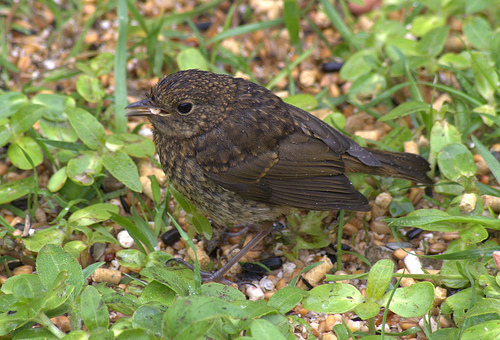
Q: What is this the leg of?
A: Small brown bird.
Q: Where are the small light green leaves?
A: On the ground.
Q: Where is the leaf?
A: On the ground.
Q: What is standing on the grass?
A: A bird.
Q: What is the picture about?
A: A bird.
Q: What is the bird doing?
A: Sitting.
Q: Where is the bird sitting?
A: On the ground.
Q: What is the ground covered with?
A: Grass, leaves and stones.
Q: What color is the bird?
A: Black and grey.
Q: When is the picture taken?
A: Daytime.